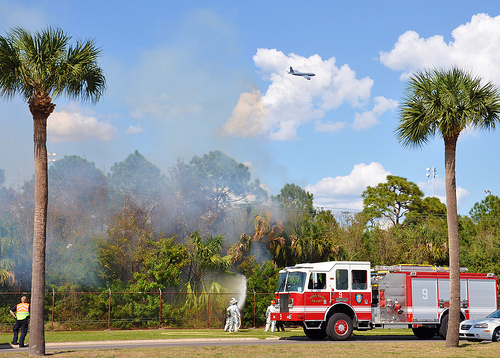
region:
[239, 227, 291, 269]
the tree is burnt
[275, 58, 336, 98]
the plane in the sky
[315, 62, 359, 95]
the cloud is white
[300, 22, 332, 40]
the sky is blue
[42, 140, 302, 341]
the forest is smoking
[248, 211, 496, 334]
the firetruck is parked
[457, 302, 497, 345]
the car is white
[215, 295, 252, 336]
the firemen are standing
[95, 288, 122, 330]
the fence is red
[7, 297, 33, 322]
the vest is yellow and orange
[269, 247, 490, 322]
fire truck parked next to palm tree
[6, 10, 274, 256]
smoke rising in the air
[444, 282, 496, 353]
white car parked next to firetruck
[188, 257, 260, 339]
people spraying water from hose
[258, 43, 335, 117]
plane flying in the sky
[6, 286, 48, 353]
man in orange and green vest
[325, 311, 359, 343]
black wheel with red rims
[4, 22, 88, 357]
tall palm tree next to a man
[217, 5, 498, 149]
white clouds in the sky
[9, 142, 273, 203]
tree canopy in the background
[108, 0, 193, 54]
this is the sky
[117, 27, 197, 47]
the sky is blue in color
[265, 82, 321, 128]
this is a cloud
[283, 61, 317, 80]
this is an aeroplane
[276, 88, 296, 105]
the cloud is white in color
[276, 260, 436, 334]
this is a fire engine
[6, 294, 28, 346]
this is a man beside the tree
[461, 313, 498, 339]
this is a saloon car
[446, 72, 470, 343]
this is a tree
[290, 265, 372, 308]
the fire engine is red and white in color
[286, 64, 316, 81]
a plane flying in the air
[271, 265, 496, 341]
a fire truck in the street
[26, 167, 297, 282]
smoke coming out from the trees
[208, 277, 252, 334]
a fire fighter fighting a tree fire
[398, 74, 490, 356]
a palm tree by the car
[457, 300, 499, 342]
a white car by the fire truck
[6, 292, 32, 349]
a man watching the fire fighters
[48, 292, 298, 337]
a fence by the trees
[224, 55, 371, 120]
a cloud in the sky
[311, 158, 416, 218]
another cloud in the sky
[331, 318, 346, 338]
front wheel of the truck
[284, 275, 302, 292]
front window of the truck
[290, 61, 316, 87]
an aeroplane in the sky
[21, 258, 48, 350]
stem of a palmtree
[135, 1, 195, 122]
part of the blue sky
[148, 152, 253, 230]
part of some smoke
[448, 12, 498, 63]
clouds in the sky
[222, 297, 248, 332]
some men in white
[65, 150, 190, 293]
section of some many trees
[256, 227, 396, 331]
part of a fire brigade